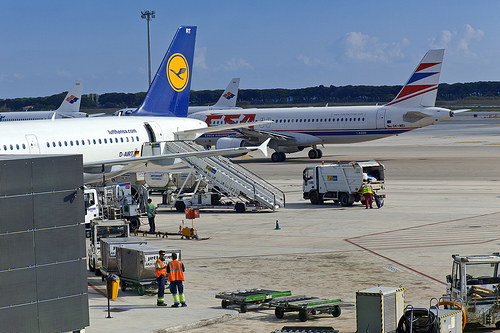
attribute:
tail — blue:
[388, 48, 443, 141]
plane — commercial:
[188, 46, 468, 166]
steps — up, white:
[163, 138, 285, 211]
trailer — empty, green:
[216, 286, 292, 312]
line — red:
[344, 239, 452, 289]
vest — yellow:
[362, 182, 372, 194]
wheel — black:
[271, 152, 280, 163]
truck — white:
[301, 161, 387, 207]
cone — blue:
[272, 217, 282, 232]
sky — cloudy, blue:
[2, 1, 498, 101]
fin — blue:
[129, 24, 200, 119]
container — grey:
[115, 242, 181, 281]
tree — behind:
[316, 85, 329, 101]